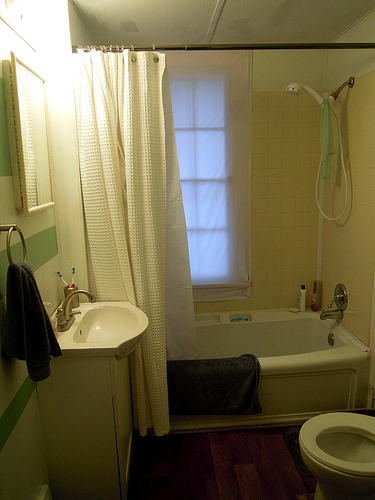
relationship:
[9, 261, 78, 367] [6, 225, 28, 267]
towel hanging from rack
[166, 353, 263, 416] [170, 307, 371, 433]
bath towel draped over bath tub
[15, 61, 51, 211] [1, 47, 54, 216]
mirror on medicine cabinet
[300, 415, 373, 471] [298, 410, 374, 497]
seat on toilet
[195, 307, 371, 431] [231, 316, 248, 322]
bath tub with soap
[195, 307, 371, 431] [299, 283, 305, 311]
bath tub with bottle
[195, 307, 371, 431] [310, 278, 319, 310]
bath tub with bottle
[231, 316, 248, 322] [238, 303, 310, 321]
soap on area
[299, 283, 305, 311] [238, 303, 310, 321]
bottle on area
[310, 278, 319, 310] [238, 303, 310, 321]
bottle on area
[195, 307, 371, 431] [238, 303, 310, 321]
bath tub with area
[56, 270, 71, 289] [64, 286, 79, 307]
toothbrushes in a glass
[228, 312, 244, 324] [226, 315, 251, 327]
handle of a razor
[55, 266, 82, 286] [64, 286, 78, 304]
toothbrushes are placed inside a glass